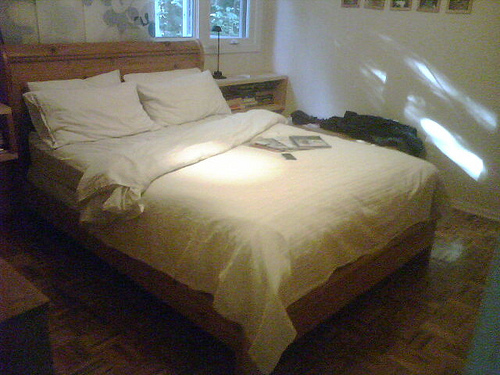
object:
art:
[337, 0, 473, 20]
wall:
[418, 26, 487, 111]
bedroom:
[0, 0, 499, 374]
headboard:
[2, 35, 207, 139]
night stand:
[216, 69, 293, 119]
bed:
[1, 36, 447, 372]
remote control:
[282, 153, 296, 161]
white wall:
[300, 10, 341, 72]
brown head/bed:
[0, 35, 208, 119]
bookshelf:
[216, 72, 289, 116]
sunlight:
[351, 15, 484, 177]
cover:
[20, 66, 453, 375]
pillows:
[123, 70, 233, 127]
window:
[151, 0, 252, 40]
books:
[247, 135, 332, 153]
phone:
[281, 152, 297, 160]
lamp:
[209, 24, 228, 80]